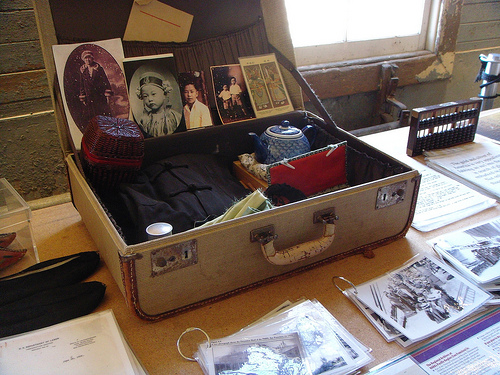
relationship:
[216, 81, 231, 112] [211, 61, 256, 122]
child in photo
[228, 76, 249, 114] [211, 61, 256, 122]
child in photo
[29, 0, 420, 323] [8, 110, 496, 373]
briefcase on desktop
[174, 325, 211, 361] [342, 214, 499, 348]
ring through picture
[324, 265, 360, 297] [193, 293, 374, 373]
ring through pictures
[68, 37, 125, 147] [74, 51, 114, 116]
picture of lady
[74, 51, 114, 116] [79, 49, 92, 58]
lady with hat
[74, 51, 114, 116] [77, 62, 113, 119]
lady with coat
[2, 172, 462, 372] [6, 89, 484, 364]
table with items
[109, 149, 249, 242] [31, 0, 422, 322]
cloth in a suitcase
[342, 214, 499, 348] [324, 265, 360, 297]
picture hold in a ring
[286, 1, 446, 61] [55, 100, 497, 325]
window behind suitcase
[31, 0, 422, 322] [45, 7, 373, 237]
suitcase with mementos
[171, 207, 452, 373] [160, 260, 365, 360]
photographs connected to rings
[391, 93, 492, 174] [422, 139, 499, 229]
abacus on papers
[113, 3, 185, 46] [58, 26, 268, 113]
envelope in pocket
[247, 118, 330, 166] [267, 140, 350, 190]
teapot next to lid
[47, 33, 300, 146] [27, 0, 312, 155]
photographs along bottom of lid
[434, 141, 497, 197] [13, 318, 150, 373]
paper with letterhead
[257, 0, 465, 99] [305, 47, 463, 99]
window with sill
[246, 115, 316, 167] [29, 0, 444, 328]
side burn in briefcase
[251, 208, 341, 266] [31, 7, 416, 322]
handle of briefcast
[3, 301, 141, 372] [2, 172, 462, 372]
papers kept in table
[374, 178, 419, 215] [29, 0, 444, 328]
lock of briefcase